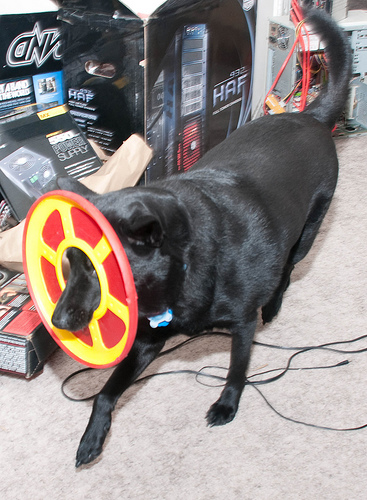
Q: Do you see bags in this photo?
A: Yes, there is a bag.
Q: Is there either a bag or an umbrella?
A: Yes, there is a bag.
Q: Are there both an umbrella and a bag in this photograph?
A: No, there is a bag but no umbrellas.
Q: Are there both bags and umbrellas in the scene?
A: No, there is a bag but no umbrellas.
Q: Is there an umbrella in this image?
A: No, there are no umbrellas.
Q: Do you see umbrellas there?
A: No, there are no umbrellas.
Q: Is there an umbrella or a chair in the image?
A: No, there are no umbrellas or chairs.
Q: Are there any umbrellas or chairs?
A: No, there are no umbrellas or chairs.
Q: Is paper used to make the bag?
A: Yes, the bag is made of paper.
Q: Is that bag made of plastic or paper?
A: The bag is made of paper.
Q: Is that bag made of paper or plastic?
A: The bag is made of paper.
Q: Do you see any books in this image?
A: No, there are no books.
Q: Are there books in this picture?
A: No, there are no books.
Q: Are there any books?
A: No, there are no books.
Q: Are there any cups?
A: No, there are no cups.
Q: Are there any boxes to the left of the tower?
A: Yes, there is a box to the left of the tower.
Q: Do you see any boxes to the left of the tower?
A: Yes, there is a box to the left of the tower.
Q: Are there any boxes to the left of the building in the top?
A: Yes, there is a box to the left of the tower.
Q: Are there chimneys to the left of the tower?
A: No, there is a box to the left of the tower.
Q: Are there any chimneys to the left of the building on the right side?
A: No, there is a box to the left of the tower.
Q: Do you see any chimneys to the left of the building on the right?
A: No, there is a box to the left of the tower.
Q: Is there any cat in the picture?
A: No, there are no cats.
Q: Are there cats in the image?
A: No, there are no cats.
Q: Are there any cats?
A: No, there are no cats.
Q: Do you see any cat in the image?
A: No, there are no cats.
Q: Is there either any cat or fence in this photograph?
A: No, there are no cats or fences.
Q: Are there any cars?
A: No, there are no cars.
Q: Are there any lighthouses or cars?
A: No, there are no cars or lighthouses.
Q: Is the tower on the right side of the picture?
A: Yes, the tower is on the right of the image.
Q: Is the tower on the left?
A: No, the tower is on the right of the image.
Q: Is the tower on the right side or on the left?
A: The tower is on the right of the image.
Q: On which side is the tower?
A: The tower is on the right of the image.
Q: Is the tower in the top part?
A: Yes, the tower is in the top of the image.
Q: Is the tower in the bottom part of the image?
A: No, the tower is in the top of the image.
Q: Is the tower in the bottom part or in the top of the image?
A: The tower is in the top of the image.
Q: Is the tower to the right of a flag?
A: No, the tower is to the right of the box.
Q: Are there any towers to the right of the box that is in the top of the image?
A: Yes, there is a tower to the right of the box.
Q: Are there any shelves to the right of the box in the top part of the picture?
A: No, there is a tower to the right of the box.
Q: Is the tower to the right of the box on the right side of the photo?
A: Yes, the tower is to the right of the box.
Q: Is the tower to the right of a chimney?
A: No, the tower is to the right of the box.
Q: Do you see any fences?
A: No, there are no fences.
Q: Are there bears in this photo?
A: No, there are no bears.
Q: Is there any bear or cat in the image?
A: No, there are no bears or cats.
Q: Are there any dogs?
A: Yes, there is a dog.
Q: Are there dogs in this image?
A: Yes, there is a dog.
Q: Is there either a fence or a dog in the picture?
A: Yes, there is a dog.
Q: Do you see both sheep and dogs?
A: No, there is a dog but no sheep.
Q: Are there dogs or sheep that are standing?
A: Yes, the dog is standing.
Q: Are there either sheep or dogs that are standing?
A: Yes, the dog is standing.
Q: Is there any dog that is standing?
A: Yes, there is a dog that is standing.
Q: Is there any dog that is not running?
A: Yes, there is a dog that is standing.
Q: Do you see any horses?
A: No, there are no horses.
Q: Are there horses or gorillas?
A: No, there are no horses or gorillas.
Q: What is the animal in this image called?
A: The animal is a dog.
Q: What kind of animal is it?
A: The animal is a dog.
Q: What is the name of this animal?
A: This is a dog.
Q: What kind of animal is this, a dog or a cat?
A: This is a dog.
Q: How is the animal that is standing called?
A: The animal is a dog.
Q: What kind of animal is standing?
A: The animal is a dog.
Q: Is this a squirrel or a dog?
A: This is a dog.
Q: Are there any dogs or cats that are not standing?
A: No, there is a dog but it is standing.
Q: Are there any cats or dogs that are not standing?
A: No, there is a dog but it is standing.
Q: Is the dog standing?
A: Yes, the dog is standing.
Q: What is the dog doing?
A: The dog is standing.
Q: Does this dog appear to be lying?
A: No, the dog is standing.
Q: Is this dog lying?
A: No, the dog is standing.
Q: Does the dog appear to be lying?
A: No, the dog is standing.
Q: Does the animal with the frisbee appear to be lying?
A: No, the dog is standing.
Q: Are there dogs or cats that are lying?
A: No, there is a dog but it is standing.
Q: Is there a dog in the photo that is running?
A: No, there is a dog but it is standing.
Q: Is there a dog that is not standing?
A: No, there is a dog but it is standing.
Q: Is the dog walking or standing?
A: The dog is standing.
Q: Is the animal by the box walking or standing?
A: The dog is standing.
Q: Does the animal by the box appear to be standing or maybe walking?
A: The dog is standing.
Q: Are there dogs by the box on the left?
A: Yes, there is a dog by the box.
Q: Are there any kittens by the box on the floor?
A: No, there is a dog by the box.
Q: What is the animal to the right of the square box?
A: The animal is a dog.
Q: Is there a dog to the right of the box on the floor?
A: Yes, there is a dog to the right of the box.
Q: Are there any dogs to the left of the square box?
A: No, the dog is to the right of the box.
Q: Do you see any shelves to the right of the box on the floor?
A: No, there is a dog to the right of the box.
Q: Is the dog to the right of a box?
A: Yes, the dog is to the right of a box.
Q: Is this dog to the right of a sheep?
A: No, the dog is to the right of a box.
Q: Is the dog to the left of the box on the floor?
A: No, the dog is to the right of the box.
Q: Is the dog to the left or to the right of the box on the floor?
A: The dog is to the right of the box.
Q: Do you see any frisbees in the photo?
A: Yes, there is a frisbee.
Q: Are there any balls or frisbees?
A: Yes, there is a frisbee.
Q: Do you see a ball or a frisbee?
A: Yes, there is a frisbee.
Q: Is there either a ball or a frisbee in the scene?
A: Yes, there is a frisbee.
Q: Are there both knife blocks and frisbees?
A: No, there is a frisbee but no knife blocks.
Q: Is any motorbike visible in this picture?
A: No, there are no motorcycles.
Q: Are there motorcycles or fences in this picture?
A: No, there are no motorcycles or fences.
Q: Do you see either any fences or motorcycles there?
A: No, there are no motorcycles or fences.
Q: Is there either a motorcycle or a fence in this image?
A: No, there are no motorcycles or fences.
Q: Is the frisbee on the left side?
A: Yes, the frisbee is on the left of the image.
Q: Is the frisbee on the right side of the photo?
A: No, the frisbee is on the left of the image.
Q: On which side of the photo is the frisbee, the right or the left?
A: The frisbee is on the left of the image.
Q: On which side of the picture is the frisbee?
A: The frisbee is on the left of the image.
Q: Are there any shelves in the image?
A: No, there are no shelves.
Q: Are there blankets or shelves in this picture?
A: No, there are no shelves or blankets.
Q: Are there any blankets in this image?
A: No, there are no blankets.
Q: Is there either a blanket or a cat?
A: No, there are no blankets or cats.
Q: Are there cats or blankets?
A: No, there are no blankets or cats.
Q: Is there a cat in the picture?
A: No, there are no cats.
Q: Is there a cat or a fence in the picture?
A: No, there are no cats or fences.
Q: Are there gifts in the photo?
A: No, there are no gifts.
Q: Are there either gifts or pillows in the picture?
A: No, there are no gifts or pillows.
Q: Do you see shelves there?
A: No, there are no shelves.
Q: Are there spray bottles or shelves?
A: No, there are no shelves or spray bottles.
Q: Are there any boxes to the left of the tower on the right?
A: Yes, there is a box to the left of the tower.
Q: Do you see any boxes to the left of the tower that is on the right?
A: Yes, there is a box to the left of the tower.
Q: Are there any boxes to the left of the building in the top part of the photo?
A: Yes, there is a box to the left of the tower.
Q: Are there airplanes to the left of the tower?
A: No, there is a box to the left of the tower.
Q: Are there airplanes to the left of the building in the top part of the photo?
A: No, there is a box to the left of the tower.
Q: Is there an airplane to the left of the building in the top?
A: No, there is a box to the left of the tower.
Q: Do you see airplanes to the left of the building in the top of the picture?
A: No, there is a box to the left of the tower.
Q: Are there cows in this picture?
A: No, there are no cows.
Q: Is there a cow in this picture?
A: No, there are no cows.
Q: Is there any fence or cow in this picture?
A: No, there are no cows or fences.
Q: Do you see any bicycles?
A: No, there are no bicycles.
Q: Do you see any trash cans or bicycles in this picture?
A: No, there are no bicycles or trash cans.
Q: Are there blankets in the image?
A: No, there are no blankets.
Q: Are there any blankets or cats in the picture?
A: No, there are no blankets or cats.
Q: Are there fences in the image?
A: No, there are no fences.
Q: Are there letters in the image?
A: Yes, there are letters.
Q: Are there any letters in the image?
A: Yes, there are letters.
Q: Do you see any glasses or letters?
A: Yes, there are letters.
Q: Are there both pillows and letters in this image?
A: No, there are letters but no pillows.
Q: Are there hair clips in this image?
A: No, there are no hair clips.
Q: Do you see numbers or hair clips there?
A: No, there are no hair clips or numbers.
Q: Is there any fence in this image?
A: No, there are no fences.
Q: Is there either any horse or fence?
A: No, there are no fences or horses.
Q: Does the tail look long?
A: Yes, the tail is long.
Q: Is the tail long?
A: Yes, the tail is long.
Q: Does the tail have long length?
A: Yes, the tail is long.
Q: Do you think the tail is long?
A: Yes, the tail is long.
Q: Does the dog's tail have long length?
A: Yes, the tail is long.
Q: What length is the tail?
A: The tail is long.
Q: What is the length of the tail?
A: The tail is long.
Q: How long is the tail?
A: The tail is long.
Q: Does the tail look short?
A: No, the tail is long.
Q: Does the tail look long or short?
A: The tail is long.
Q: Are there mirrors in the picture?
A: No, there are no mirrors.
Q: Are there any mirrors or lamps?
A: No, there are no mirrors or lamps.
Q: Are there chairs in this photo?
A: No, there are no chairs.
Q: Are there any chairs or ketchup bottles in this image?
A: No, there are no chairs or ketchup bottles.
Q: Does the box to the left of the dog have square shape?
A: Yes, the box is square.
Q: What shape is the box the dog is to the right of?
A: The box is square.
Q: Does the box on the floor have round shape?
A: No, the box is square.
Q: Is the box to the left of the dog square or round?
A: The box is square.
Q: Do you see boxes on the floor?
A: Yes, there is a box on the floor.